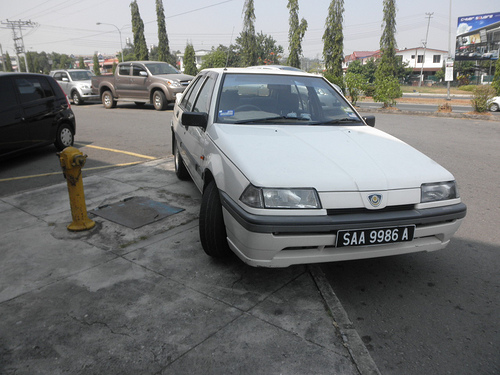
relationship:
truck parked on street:
[97, 60, 190, 105] [88, 107, 162, 150]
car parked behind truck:
[62, 68, 95, 99] [97, 60, 190, 105]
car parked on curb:
[180, 68, 457, 274] [100, 163, 190, 312]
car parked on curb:
[62, 68, 95, 99] [100, 163, 190, 312]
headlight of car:
[259, 186, 322, 208] [62, 68, 95, 99]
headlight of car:
[425, 181, 455, 200] [62, 68, 95, 99]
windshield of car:
[225, 74, 343, 125] [180, 68, 457, 274]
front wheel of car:
[200, 186, 222, 263] [180, 68, 457, 274]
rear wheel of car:
[173, 149, 188, 177] [180, 68, 457, 274]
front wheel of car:
[73, 92, 81, 102] [62, 68, 95, 99]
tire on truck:
[154, 92, 171, 112] [97, 60, 190, 105]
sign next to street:
[460, 18, 496, 58] [88, 107, 162, 150]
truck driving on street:
[97, 60, 190, 105] [88, 107, 162, 150]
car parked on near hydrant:
[180, 68, 457, 274] [53, 146, 100, 236]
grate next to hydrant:
[97, 196, 188, 229] [53, 146, 100, 236]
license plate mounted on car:
[340, 230, 415, 240] [180, 68, 457, 274]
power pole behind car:
[9, 21, 25, 66] [62, 68, 95, 99]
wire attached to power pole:
[42, 20, 72, 32] [9, 21, 25, 66]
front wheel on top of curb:
[200, 186, 222, 263] [100, 163, 190, 312]